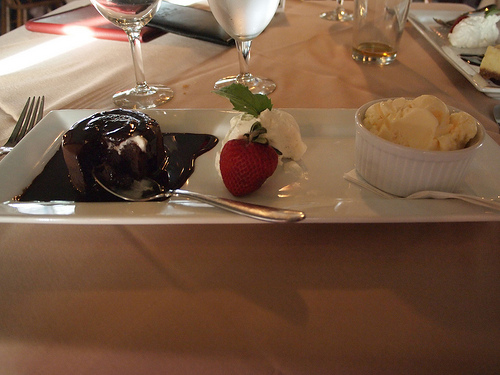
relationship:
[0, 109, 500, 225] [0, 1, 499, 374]
platter on table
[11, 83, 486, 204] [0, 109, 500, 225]
desserts on platter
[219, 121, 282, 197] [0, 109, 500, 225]
strawberry on platter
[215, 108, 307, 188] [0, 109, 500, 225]
whipped cream on platter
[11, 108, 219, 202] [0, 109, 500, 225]
chocolate mousse on platter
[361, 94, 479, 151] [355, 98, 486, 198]
desserts in bowl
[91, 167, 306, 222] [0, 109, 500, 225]
spoon on platter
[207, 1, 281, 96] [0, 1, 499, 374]
water glass on table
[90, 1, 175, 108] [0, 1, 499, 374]
wine glass on table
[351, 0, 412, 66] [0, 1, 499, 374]
glass on table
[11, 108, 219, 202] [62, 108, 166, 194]
chocolate mousse around chocolate cake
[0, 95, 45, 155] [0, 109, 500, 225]
fork next to platter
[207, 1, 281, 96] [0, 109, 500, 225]
water glass next to platter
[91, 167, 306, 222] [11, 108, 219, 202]
spoon in chocolate mousse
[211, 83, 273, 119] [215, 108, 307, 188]
mint leaf on whipped cream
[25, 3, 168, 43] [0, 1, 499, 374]
tablet on table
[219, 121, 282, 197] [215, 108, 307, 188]
strawberry next to whipped cream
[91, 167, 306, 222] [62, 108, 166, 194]
spoon in chocolate cake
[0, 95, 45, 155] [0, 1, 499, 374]
fork on table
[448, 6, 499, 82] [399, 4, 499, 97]
desserts on platter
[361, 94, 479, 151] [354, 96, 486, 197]
desserts in ramekin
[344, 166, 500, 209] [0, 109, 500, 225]
napkin on platter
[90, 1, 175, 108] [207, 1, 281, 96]
wine glass next to water glass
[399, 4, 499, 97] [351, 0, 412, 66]
platter next to glass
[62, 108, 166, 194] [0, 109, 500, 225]
chocolate cake on platter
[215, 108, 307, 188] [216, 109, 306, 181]
whipped cream in a scoop